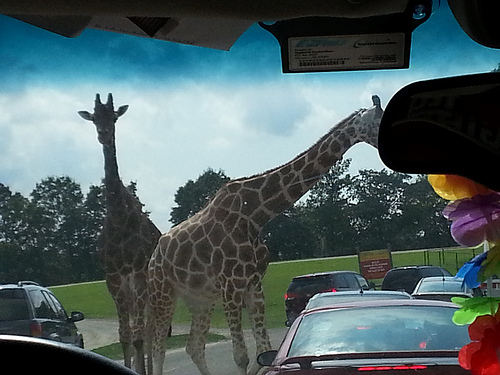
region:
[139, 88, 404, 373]
giraffe leaning head over a car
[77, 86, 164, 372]
giraffe standing up tall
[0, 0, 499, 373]
windshield of car people are in who took the picture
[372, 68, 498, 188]
rear view mirror of the car people are in who took the picture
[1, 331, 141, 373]
steering wheel of car people are in who took the picture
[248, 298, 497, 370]
red car in front of the car people are in who took the picture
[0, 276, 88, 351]
dark blue SUV type vehicle going around the tall giraffe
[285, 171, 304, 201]
brown spot on giraffe with neck bent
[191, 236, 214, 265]
brown spot on giraffe with neck bent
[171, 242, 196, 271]
brown spot on giraffe with neck bent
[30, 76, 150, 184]
giraffe is looking in the camera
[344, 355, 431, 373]
the brake lights are on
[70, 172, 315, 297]
the giraffe is brown and beige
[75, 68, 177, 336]
the giraffe is tall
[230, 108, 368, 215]
the neck is long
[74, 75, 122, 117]
horns on the giraffes head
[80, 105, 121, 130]
the eyes are open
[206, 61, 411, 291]
the giraffe is looking right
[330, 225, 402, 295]
a sign ahead of the cars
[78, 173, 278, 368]
the giraffes are on the road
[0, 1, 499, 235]
a blue and white cloudy sky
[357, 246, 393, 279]
a yellow and brown sign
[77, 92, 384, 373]
two giraffe's in a road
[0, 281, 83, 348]
a gray minivan on a road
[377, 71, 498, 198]
a rear view mirror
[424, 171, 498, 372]
a colorful lei hanging from a rear view mirror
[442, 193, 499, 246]
a purple flower on a lei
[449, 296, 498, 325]
a green flower on a lei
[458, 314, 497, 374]
a red flower on a lei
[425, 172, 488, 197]
a yellow flower on a lei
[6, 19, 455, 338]
this is nature setting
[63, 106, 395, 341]
this is a safari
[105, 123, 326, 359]
these are giraffes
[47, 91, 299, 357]
the giraffes are very tall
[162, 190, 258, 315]
the giraffes are spotted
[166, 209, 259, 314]
the giraffes are tan and brown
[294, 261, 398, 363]
thse are cars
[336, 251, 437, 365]
the cars are in a line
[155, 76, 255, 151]
the sky is very cloudy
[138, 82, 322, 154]
the clouds are white and gray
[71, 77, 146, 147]
head of the giraffe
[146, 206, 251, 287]
brown and white giraffes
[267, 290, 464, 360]
back of the car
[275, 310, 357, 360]
light hitting the car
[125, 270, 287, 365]
legs of the animal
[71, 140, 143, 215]
neck of the giraffe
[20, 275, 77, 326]
windows on side of car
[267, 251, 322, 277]
grass in the distance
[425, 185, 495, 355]
colorful stuff in car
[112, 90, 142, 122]
ear of the giraffe